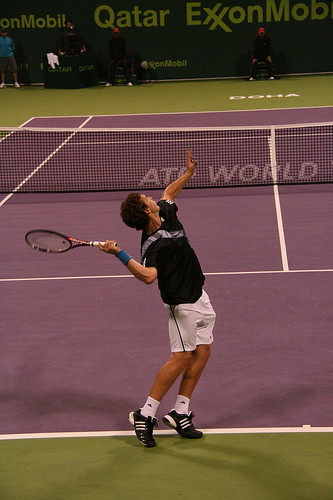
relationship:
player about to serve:
[101, 149, 218, 449] [22, 124, 205, 257]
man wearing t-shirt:
[1, 25, 22, 92] [1, 36, 20, 58]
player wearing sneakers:
[101, 149, 218, 449] [125, 408, 204, 448]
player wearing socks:
[101, 149, 218, 449] [138, 395, 194, 418]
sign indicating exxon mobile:
[1, 2, 332, 31] [182, 2, 333, 32]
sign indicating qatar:
[1, 2, 332, 31] [93, 4, 172, 28]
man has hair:
[101, 149, 218, 449] [118, 192, 151, 234]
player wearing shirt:
[101, 149, 218, 449] [138, 199, 207, 305]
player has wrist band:
[101, 149, 218, 449] [114, 250, 134, 268]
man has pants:
[101, 149, 218, 449] [162, 285, 218, 353]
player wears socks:
[101, 149, 218, 449] [138, 395, 194, 418]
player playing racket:
[101, 149, 218, 449] [22, 228, 118, 254]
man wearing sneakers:
[101, 149, 218, 449] [125, 408, 204, 448]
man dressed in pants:
[1, 25, 22, 92] [162, 285, 218, 353]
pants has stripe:
[162, 285, 218, 353] [169, 304, 189, 353]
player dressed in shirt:
[101, 149, 218, 449] [138, 199, 207, 305]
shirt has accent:
[138, 199, 207, 305] [140, 227, 186, 256]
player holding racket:
[101, 149, 218, 449] [22, 228, 121, 254]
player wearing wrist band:
[101, 149, 218, 449] [114, 250, 134, 268]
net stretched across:
[1, 120, 333, 193] [1, 104, 332, 208]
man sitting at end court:
[245, 24, 278, 83] [2, 63, 332, 95]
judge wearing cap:
[245, 24, 278, 83] [256, 27, 266, 35]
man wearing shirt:
[1, 25, 22, 92] [1, 36, 20, 58]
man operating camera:
[54, 19, 88, 55] [62, 34, 80, 55]